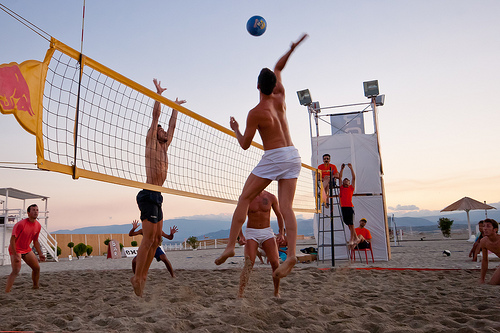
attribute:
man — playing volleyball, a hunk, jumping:
[213, 35, 311, 278]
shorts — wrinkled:
[251, 146, 304, 181]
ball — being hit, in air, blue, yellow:
[246, 15, 268, 37]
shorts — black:
[137, 186, 165, 223]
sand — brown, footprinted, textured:
[1, 232, 498, 332]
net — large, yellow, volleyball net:
[1, 3, 329, 216]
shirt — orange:
[338, 184, 355, 209]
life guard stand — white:
[1, 188, 61, 265]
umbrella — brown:
[442, 197, 497, 240]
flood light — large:
[364, 80, 380, 96]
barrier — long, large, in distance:
[48, 233, 142, 259]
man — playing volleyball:
[4, 205, 46, 290]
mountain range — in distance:
[49, 206, 499, 241]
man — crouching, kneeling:
[471, 220, 498, 286]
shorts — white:
[244, 226, 277, 244]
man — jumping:
[129, 79, 187, 298]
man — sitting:
[349, 218, 374, 251]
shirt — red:
[352, 227, 371, 239]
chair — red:
[349, 242, 376, 264]